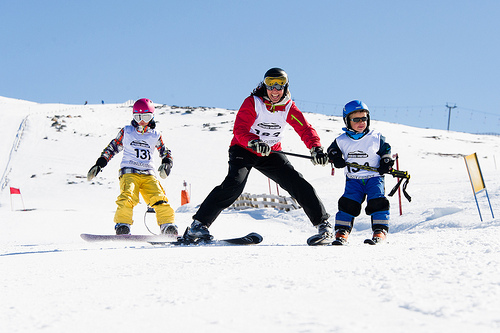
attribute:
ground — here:
[4, 97, 485, 332]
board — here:
[149, 234, 266, 250]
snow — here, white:
[0, 97, 498, 329]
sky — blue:
[2, 1, 499, 140]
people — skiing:
[83, 66, 399, 247]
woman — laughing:
[186, 69, 337, 250]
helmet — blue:
[340, 97, 367, 130]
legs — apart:
[191, 143, 324, 233]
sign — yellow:
[463, 150, 486, 196]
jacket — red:
[234, 93, 314, 157]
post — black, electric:
[445, 99, 459, 126]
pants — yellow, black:
[115, 167, 174, 229]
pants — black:
[190, 140, 325, 226]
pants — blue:
[331, 175, 398, 231]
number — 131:
[131, 145, 152, 161]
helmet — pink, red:
[131, 96, 157, 122]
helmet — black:
[264, 64, 291, 89]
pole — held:
[385, 153, 410, 211]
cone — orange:
[178, 188, 189, 205]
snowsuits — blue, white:
[105, 93, 407, 224]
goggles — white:
[132, 106, 159, 125]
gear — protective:
[324, 101, 398, 217]